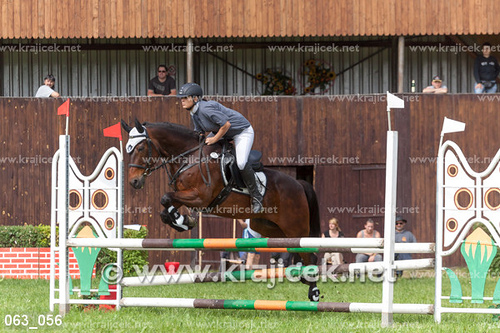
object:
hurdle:
[65, 235, 384, 255]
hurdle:
[67, 295, 434, 315]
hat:
[396, 217, 407, 224]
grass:
[0, 272, 500, 333]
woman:
[174, 82, 265, 214]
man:
[354, 217, 383, 263]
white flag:
[384, 90, 405, 130]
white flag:
[438, 115, 466, 141]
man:
[384, 215, 419, 261]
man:
[147, 64, 177, 97]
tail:
[297, 179, 324, 238]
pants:
[231, 125, 254, 168]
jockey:
[174, 82, 267, 214]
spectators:
[31, 42, 498, 98]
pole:
[49, 127, 124, 316]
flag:
[57, 98, 71, 117]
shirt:
[189, 99, 251, 138]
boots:
[229, 161, 266, 214]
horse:
[118, 114, 325, 302]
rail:
[117, 222, 390, 314]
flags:
[383, 90, 466, 146]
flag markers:
[56, 98, 121, 144]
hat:
[176, 82, 203, 100]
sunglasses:
[181, 95, 192, 99]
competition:
[118, 81, 329, 302]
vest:
[190, 99, 252, 138]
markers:
[56, 97, 124, 146]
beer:
[410, 79, 415, 93]